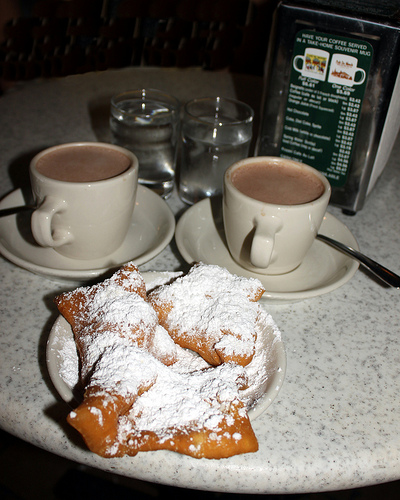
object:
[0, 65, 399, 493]
table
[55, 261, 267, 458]
pastry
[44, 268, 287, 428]
plate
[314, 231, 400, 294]
spoon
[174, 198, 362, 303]
saucer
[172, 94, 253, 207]
glass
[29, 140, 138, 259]
cup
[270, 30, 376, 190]
sign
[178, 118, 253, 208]
water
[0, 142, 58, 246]
shadow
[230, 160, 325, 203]
coffee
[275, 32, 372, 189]
menu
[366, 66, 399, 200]
napkin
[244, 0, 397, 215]
napkin dispenser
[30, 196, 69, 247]
handle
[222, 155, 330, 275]
cup